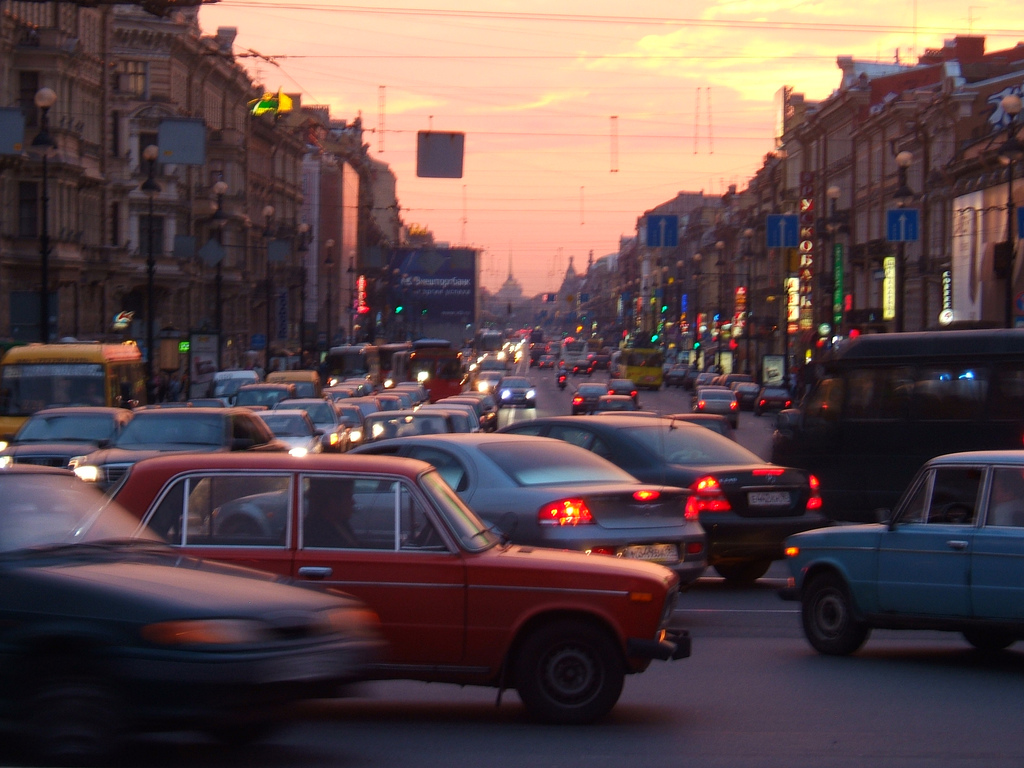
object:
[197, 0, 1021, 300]
sunset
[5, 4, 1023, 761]
scene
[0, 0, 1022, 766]
outside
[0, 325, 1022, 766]
road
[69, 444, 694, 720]
vehicle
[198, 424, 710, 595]
vehicle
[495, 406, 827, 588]
vehicle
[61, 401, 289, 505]
vehicle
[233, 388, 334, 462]
vehicle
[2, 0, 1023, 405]
background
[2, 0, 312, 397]
building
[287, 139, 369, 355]
building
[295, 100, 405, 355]
building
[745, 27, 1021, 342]
building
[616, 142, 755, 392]
building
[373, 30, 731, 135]
cloud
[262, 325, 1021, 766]
road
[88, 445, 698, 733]
car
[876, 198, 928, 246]
banner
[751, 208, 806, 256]
banner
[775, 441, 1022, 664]
car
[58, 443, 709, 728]
sedan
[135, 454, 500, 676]
doors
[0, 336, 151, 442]
truck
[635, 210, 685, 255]
banner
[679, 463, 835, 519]
taillights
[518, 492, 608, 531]
taillight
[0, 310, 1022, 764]
cars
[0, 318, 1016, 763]
traffic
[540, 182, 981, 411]
stores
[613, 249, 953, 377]
lights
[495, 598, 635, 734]
tire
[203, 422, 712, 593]
car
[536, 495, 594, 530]
tail light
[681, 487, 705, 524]
tail light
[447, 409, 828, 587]
car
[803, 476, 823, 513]
tail light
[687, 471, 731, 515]
tail light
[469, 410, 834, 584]
car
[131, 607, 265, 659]
light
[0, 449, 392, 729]
car